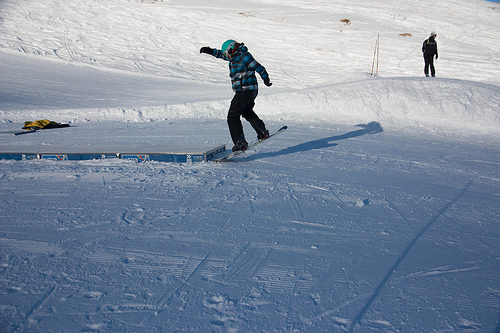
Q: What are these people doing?
A: Snowboarding.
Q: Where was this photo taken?
A: Outside, in the snow.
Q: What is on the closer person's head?
A: A helmet.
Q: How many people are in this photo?
A: Two.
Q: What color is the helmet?
A: Blue.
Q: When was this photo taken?
A: During the winter months.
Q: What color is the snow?
A: White.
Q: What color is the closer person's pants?
A: Black.